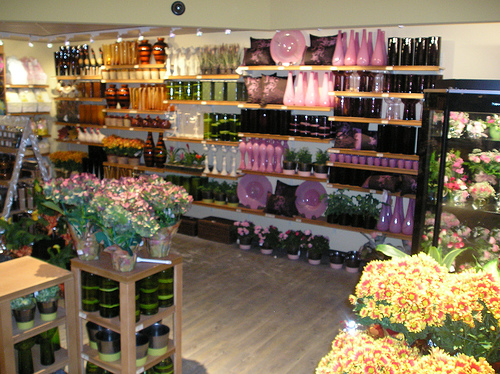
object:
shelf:
[328, 90, 425, 100]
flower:
[405, 319, 423, 333]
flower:
[462, 313, 473, 324]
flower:
[404, 291, 419, 303]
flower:
[379, 287, 397, 300]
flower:
[395, 295, 408, 308]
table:
[69, 244, 185, 374]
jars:
[80, 271, 120, 319]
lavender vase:
[402, 196, 415, 234]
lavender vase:
[344, 30, 357, 66]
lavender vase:
[376, 202, 390, 231]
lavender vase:
[389, 196, 403, 233]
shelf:
[191, 195, 414, 242]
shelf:
[239, 169, 328, 182]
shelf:
[328, 90, 425, 99]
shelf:
[328, 115, 422, 127]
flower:
[418, 295, 433, 308]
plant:
[94, 190, 160, 273]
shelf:
[69, 243, 185, 285]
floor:
[66, 231, 363, 374]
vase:
[370, 28, 384, 65]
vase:
[355, 28, 369, 66]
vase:
[332, 29, 345, 66]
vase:
[319, 71, 331, 106]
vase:
[305, 71, 318, 107]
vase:
[294, 71, 305, 106]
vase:
[282, 71, 295, 107]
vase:
[274, 140, 283, 173]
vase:
[259, 139, 267, 172]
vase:
[251, 139, 260, 171]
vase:
[245, 139, 253, 170]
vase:
[239, 137, 247, 169]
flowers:
[408, 267, 425, 279]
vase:
[152, 37, 170, 64]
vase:
[137, 39, 153, 65]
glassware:
[237, 137, 289, 174]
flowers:
[421, 111, 499, 275]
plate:
[295, 180, 329, 220]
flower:
[306, 234, 330, 265]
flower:
[278, 229, 308, 260]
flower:
[234, 219, 259, 255]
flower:
[254, 224, 284, 248]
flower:
[328, 251, 347, 269]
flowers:
[359, 307, 369, 318]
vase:
[266, 140, 275, 173]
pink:
[270, 29, 306, 65]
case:
[408, 87, 498, 272]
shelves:
[102, 161, 166, 174]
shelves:
[69, 245, 185, 374]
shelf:
[168, 74, 241, 80]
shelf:
[53, 75, 103, 81]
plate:
[269, 28, 306, 66]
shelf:
[236, 64, 441, 71]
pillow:
[304, 32, 346, 65]